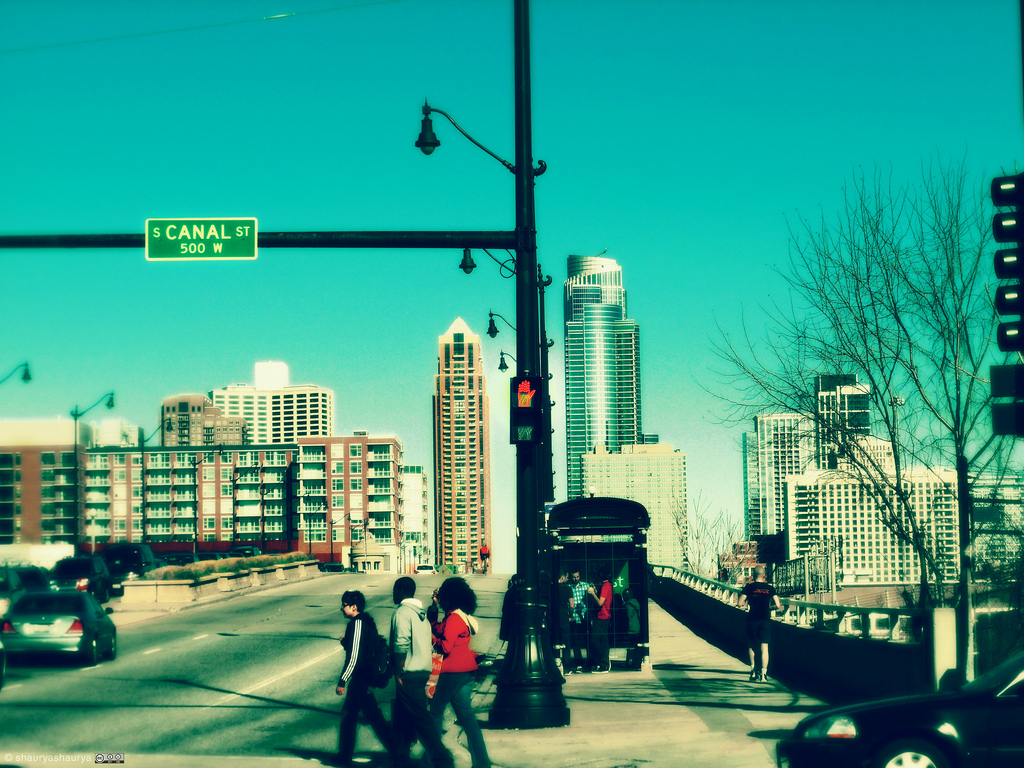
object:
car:
[0, 592, 115, 667]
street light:
[409, 102, 569, 728]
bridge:
[0, 563, 1024, 768]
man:
[588, 565, 613, 674]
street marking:
[192, 633, 209, 639]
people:
[426, 577, 491, 768]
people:
[567, 566, 625, 661]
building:
[434, 318, 493, 575]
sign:
[145, 218, 258, 261]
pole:
[0, 232, 517, 249]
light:
[413, 96, 441, 155]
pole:
[487, 0, 569, 740]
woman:
[331, 590, 394, 768]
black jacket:
[337, 612, 381, 688]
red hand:
[518, 380, 536, 407]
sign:
[510, 377, 542, 444]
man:
[738, 566, 780, 684]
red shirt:
[597, 581, 612, 619]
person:
[568, 570, 597, 674]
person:
[550, 571, 573, 676]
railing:
[649, 563, 1024, 698]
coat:
[427, 606, 478, 674]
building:
[563, 255, 640, 501]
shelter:
[532, 497, 649, 670]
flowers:
[145, 551, 310, 581]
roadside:
[0, 556, 453, 768]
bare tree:
[691, 146, 1024, 640]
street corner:
[479, 562, 1024, 768]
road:
[0, 570, 1024, 764]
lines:
[209, 644, 346, 708]